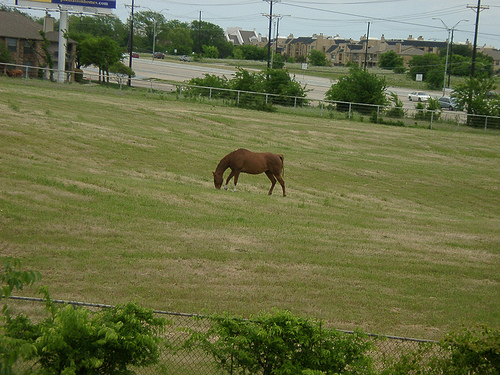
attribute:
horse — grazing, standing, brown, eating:
[213, 150, 286, 198]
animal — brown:
[213, 148, 286, 196]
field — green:
[2, 73, 499, 356]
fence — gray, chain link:
[0, 62, 499, 134]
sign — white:
[13, 0, 117, 19]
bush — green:
[325, 65, 389, 115]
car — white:
[408, 90, 433, 104]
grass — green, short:
[1, 73, 498, 298]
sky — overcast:
[3, 3, 500, 55]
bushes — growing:
[185, 65, 313, 112]